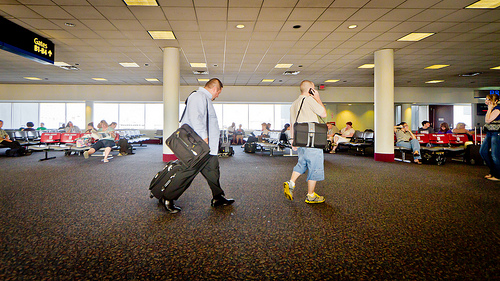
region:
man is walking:
[161, 79, 244, 211]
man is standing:
[284, 74, 334, 204]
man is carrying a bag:
[292, 118, 325, 143]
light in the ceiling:
[232, 22, 252, 33]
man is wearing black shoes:
[209, 189, 235, 205]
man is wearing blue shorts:
[297, 148, 326, 177]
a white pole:
[370, 53, 395, 156]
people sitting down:
[72, 120, 119, 152]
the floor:
[158, 219, 383, 274]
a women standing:
[480, 94, 497, 189]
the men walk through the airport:
[134, 72, 358, 219]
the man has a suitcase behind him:
[146, 150, 183, 210]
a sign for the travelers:
[4, 9, 56, 67]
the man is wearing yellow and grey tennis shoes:
[271, 178, 331, 204]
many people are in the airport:
[1, 104, 497, 173]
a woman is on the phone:
[477, 90, 499, 182]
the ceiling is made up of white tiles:
[105, 5, 437, 82]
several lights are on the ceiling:
[4, 8, 490, 91]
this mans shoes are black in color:
[156, 192, 242, 217]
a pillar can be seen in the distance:
[370, 50, 403, 162]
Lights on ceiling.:
[68, 0, 497, 79]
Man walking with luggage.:
[143, 79, 235, 211]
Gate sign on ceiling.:
[1, 17, 59, 67]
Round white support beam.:
[368, 48, 399, 163]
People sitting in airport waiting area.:
[10, 119, 140, 161]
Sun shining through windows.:
[35, 101, 166, 128]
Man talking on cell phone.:
[282, 77, 327, 207]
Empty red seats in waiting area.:
[417, 129, 467, 146]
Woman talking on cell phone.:
[480, 91, 497, 193]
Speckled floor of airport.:
[5, 214, 498, 278]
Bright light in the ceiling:
[143, 21, 183, 47]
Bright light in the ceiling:
[119, 0, 164, 14]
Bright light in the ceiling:
[228, 14, 253, 35]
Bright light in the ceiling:
[266, 53, 294, 75]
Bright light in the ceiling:
[250, 70, 282, 88]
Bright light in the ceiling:
[189, 54, 219, 69]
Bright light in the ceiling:
[397, 19, 427, 47]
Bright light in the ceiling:
[421, 56, 450, 71]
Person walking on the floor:
[271, 69, 342, 233]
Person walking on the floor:
[114, 41, 241, 215]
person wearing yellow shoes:
[266, 77, 338, 208]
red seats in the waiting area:
[31, 119, 471, 150]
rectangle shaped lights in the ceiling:
[25, 29, 494, 90]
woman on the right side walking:
[469, 93, 496, 185]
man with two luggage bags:
[148, 74, 240, 211]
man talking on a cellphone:
[278, 79, 332, 204]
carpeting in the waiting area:
[7, 127, 499, 273]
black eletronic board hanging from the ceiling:
[3, 22, 60, 64]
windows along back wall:
[3, 99, 471, 128]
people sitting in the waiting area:
[44, 111, 477, 160]